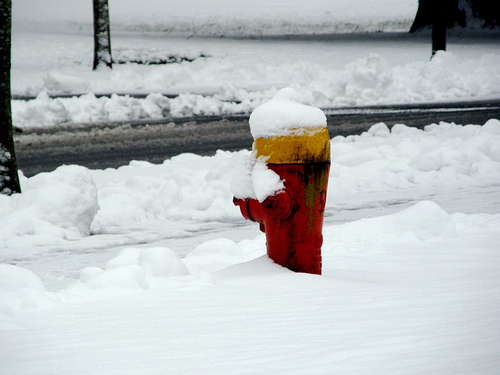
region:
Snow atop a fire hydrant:
[241, 86, 330, 148]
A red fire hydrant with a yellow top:
[230, 107, 344, 300]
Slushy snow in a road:
[32, 125, 160, 154]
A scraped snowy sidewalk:
[372, 173, 494, 235]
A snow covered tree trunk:
[83, 10, 134, 74]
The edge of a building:
[414, 2, 491, 37]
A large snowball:
[31, 155, 118, 246]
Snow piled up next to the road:
[27, 86, 214, 121]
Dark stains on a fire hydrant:
[288, 130, 332, 192]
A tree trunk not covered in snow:
[428, 3, 451, 60]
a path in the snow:
[358, 157, 498, 251]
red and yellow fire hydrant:
[227, 85, 344, 281]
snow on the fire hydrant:
[233, 84, 331, 283]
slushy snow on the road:
[17, 83, 497, 185]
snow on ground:
[368, 259, 495, 364]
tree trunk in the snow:
[418, 4, 460, 74]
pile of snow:
[26, 159, 108, 244]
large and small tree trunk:
[395, 0, 498, 58]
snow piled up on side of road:
[350, 50, 496, 128]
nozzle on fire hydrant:
[259, 187, 302, 239]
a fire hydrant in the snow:
[198, 84, 358, 281]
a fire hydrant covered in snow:
[196, 64, 370, 285]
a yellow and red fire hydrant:
[155, 80, 438, 323]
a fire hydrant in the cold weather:
[210, 94, 410, 289]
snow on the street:
[11, 40, 218, 355]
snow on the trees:
[85, 7, 162, 90]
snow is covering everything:
[67, 30, 442, 312]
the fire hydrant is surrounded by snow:
[176, 69, 354, 304]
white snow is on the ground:
[185, 59, 393, 337]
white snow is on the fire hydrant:
[177, 65, 394, 347]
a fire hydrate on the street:
[195, 67, 347, 308]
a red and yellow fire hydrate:
[222, 93, 366, 318]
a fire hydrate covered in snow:
[213, 57, 340, 287]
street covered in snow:
[25, 62, 204, 316]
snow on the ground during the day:
[166, 33, 396, 308]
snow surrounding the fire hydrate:
[172, 85, 393, 346]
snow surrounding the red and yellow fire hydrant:
[172, 38, 394, 360]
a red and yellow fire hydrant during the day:
[168, 80, 395, 322]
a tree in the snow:
[62, 0, 208, 100]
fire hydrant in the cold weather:
[5, 17, 432, 332]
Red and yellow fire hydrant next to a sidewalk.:
[215, 98, 367, 285]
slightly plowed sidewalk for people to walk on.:
[14, 213, 251, 285]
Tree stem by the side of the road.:
[0, 0, 21, 196]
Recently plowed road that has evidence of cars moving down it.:
[29, 89, 481, 169]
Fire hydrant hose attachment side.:
[222, 165, 263, 235]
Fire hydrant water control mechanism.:
[256, 180, 300, 230]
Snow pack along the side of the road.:
[18, 272, 299, 374]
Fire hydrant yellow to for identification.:
[239, 89, 337, 166]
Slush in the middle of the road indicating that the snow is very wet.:
[18, 117, 230, 154]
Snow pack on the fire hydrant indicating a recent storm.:
[227, 148, 294, 206]